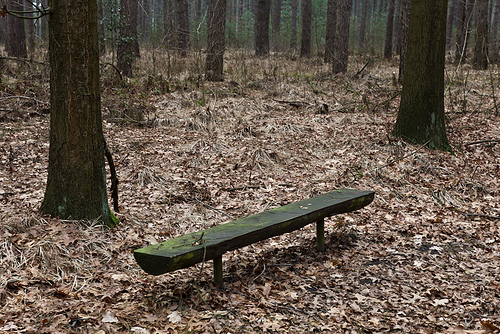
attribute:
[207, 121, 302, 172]
grass — dry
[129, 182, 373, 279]
bench — wooden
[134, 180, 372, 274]
seat — bench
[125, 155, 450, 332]
bench forest — small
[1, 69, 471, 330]
ground — leaf strewn forest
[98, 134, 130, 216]
branch — fallen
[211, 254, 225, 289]
support pole — wooden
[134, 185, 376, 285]
bench — wooden